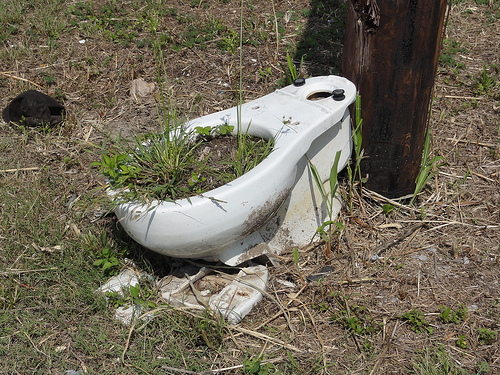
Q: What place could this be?
A: It is a field.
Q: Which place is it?
A: It is a field.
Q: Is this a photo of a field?
A: Yes, it is showing a field.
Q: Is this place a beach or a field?
A: It is a field.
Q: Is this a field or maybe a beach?
A: It is a field.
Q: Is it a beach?
A: No, it is a field.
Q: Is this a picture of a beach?
A: No, the picture is showing a field.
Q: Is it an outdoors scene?
A: Yes, it is outdoors.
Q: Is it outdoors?
A: Yes, it is outdoors.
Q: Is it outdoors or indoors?
A: It is outdoors.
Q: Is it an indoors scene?
A: No, it is outdoors.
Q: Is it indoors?
A: No, it is outdoors.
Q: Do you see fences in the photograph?
A: No, there are no fences.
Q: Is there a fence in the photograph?
A: No, there are no fences.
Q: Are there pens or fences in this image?
A: No, there are no fences or pens.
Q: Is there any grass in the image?
A: Yes, there is grass.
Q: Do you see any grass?
A: Yes, there is grass.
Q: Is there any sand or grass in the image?
A: Yes, there is grass.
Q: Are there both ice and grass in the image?
A: No, there is grass but no ice.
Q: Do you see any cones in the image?
A: No, there are no cones.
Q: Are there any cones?
A: No, there are no cones.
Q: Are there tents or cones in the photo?
A: No, there are no cones or tents.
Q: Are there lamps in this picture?
A: No, there are no lamps.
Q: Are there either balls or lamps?
A: No, there are no lamps or balls.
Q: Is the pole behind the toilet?
A: Yes, the pole is behind the toilet.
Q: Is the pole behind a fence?
A: No, the pole is behind the toilet.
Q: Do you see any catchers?
A: No, there are no catchers.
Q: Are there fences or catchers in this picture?
A: No, there are no catchers or fences.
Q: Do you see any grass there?
A: Yes, there is grass.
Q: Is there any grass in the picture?
A: Yes, there is grass.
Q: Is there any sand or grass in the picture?
A: Yes, there is grass.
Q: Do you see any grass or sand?
A: Yes, there is grass.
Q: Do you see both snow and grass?
A: No, there is grass but no snow.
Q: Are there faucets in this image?
A: No, there are no faucets.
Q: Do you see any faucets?
A: No, there are no faucets.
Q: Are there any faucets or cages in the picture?
A: No, there are no faucets or cages.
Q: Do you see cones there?
A: No, there are no cones.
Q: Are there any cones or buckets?
A: No, there are no cones or buckets.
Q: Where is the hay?
A: The hay is on the field.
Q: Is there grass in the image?
A: Yes, there is grass.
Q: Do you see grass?
A: Yes, there is grass.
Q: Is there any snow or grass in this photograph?
A: Yes, there is grass.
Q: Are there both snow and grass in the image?
A: No, there is grass but no snow.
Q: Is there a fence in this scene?
A: No, there are no fences.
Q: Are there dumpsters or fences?
A: No, there are no fences or dumpsters.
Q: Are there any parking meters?
A: No, there are no parking meters.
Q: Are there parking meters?
A: No, there are no parking meters.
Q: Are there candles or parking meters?
A: No, there are no parking meters or candles.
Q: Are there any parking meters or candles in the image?
A: No, there are no parking meters or candles.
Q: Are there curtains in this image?
A: No, there are no curtains.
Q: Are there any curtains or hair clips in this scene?
A: No, there are no curtains or hair clips.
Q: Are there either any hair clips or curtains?
A: No, there are no curtains or hair clips.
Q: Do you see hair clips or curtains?
A: No, there are no curtains or hair clips.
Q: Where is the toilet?
A: The toilet is on the field.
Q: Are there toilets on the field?
A: Yes, there is a toilet on the field.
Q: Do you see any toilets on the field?
A: Yes, there is a toilet on the field.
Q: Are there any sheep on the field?
A: No, there is a toilet on the field.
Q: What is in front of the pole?
A: The toilet is in front of the pole.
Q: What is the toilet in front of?
A: The toilet is in front of the pole.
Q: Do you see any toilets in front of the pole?
A: Yes, there is a toilet in front of the pole.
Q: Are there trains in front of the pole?
A: No, there is a toilet in front of the pole.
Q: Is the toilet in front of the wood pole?
A: Yes, the toilet is in front of the pole.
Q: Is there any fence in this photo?
A: No, there are no fences.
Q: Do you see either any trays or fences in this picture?
A: No, there are no fences or trays.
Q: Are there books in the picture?
A: No, there are no books.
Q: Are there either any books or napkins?
A: No, there are no books or napkins.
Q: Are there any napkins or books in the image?
A: No, there are no books or napkins.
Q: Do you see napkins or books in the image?
A: No, there are no books or napkins.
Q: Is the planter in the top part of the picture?
A: Yes, the planter is in the top of the image.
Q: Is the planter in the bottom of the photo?
A: No, the planter is in the top of the image.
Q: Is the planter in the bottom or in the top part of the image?
A: The planter is in the top of the image.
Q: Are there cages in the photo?
A: No, there are no cages.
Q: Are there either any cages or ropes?
A: No, there are no cages or ropes.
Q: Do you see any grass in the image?
A: Yes, there is grass.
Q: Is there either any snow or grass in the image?
A: Yes, there is grass.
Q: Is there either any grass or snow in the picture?
A: Yes, there is grass.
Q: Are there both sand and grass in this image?
A: No, there is grass but no sand.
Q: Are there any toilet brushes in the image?
A: No, there are no toilet brushes.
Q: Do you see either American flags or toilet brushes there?
A: No, there are no toilet brushes or American flags.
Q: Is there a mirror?
A: No, there are no mirrors.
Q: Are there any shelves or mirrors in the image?
A: No, there are no mirrors or shelves.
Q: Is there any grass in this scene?
A: Yes, there is grass.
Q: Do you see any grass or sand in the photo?
A: Yes, there is grass.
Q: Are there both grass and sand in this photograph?
A: No, there is grass but no sand.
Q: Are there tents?
A: No, there are no tents.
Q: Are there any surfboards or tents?
A: No, there are no tents or surfboards.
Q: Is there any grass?
A: Yes, there is grass.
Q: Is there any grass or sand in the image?
A: Yes, there is grass.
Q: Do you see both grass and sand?
A: No, there is grass but no sand.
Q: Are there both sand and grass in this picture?
A: No, there is grass but no sand.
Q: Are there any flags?
A: No, there are no flags.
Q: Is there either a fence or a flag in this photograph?
A: No, there are no flags or fences.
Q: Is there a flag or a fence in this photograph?
A: No, there are no flags or fences.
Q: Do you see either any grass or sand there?
A: Yes, there is grass.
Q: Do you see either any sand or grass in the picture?
A: Yes, there is grass.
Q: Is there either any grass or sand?
A: Yes, there is grass.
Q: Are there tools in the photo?
A: No, there are no tools.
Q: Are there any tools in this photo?
A: No, there are no tools.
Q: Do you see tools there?
A: No, there are no tools.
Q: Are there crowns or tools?
A: No, there are no tools or crowns.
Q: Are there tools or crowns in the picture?
A: No, there are no tools or crowns.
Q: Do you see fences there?
A: No, there are no fences.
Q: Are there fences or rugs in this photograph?
A: No, there are no fences or rugs.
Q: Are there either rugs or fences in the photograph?
A: No, there are no fences or rugs.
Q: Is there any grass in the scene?
A: Yes, there is grass.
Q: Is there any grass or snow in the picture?
A: Yes, there is grass.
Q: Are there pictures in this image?
A: No, there are no pictures.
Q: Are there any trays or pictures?
A: No, there are no pictures or trays.